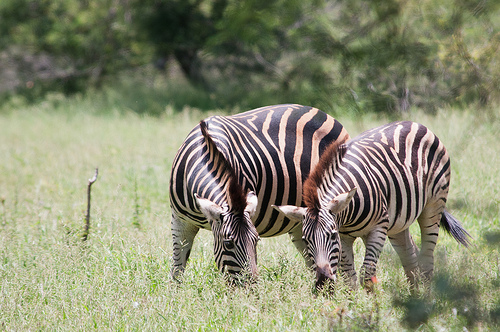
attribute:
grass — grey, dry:
[0, 77, 499, 328]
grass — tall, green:
[10, 116, 169, 330]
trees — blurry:
[0, 0, 499, 112]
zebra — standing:
[262, 135, 460, 228]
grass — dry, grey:
[0, 212, 138, 288]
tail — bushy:
[440, 206, 476, 250]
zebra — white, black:
[291, 119, 477, 299]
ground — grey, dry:
[317, 115, 396, 181]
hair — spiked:
[199, 120, 246, 238]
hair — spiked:
[302, 134, 349, 219]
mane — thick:
[187, 117, 253, 252]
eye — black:
[222, 238, 239, 249]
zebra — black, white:
[168, 99, 350, 297]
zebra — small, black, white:
[270, 117, 472, 297]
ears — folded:
[191, 190, 223, 224]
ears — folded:
[239, 188, 259, 216]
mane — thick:
[195, 119, 252, 216]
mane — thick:
[300, 133, 345, 215]